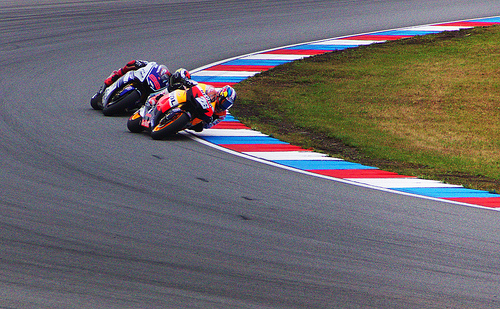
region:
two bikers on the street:
[79, 28, 240, 180]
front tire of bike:
[144, 98, 201, 151]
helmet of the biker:
[211, 74, 243, 116]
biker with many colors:
[129, 82, 248, 156]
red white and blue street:
[268, 135, 388, 203]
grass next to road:
[313, 85, 406, 142]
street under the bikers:
[82, 145, 192, 230]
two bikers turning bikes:
[71, 54, 263, 161]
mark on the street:
[159, 160, 239, 220]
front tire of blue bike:
[103, 81, 143, 113]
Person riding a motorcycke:
[70, 42, 161, 104]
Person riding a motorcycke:
[135, 63, 218, 145]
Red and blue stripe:
[322, 153, 376, 193]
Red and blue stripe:
[423, 177, 498, 234]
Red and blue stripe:
[220, 40, 262, 91]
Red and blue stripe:
[256, 27, 321, 89]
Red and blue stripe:
[327, 15, 374, 69]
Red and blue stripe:
[369, 10, 429, 53]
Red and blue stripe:
[440, 9, 477, 51]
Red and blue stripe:
[238, 117, 293, 179]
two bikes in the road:
[90, 16, 312, 208]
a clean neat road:
[1, 106, 369, 306]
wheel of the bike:
[148, 113, 200, 142]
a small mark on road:
[183, 159, 233, 201]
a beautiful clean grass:
[264, 46, 476, 211]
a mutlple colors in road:
[234, 129, 493, 229]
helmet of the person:
[212, 88, 244, 110]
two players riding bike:
[63, 1, 275, 187]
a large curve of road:
[62, 5, 435, 255]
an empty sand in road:
[400, 59, 499, 161]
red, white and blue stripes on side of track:
[179, 12, 497, 219]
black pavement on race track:
[1, 0, 496, 307]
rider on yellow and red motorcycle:
[127, 83, 236, 138]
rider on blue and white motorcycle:
[90, 60, 188, 120]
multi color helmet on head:
[217, 85, 234, 109]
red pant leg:
[101, 58, 146, 87]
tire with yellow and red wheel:
[150, 105, 191, 139]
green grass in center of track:
[227, 23, 498, 191]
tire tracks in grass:
[235, 98, 361, 160]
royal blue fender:
[116, 85, 136, 97]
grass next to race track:
[226, 22, 498, 189]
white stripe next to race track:
[355, 178, 452, 185]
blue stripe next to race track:
[271, 158, 375, 169]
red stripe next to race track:
[311, 167, 401, 177]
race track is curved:
[1, 1, 499, 307]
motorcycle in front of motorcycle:
[126, 77, 234, 137]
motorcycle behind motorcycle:
[91, 56, 189, 116]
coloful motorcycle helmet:
[218, 83, 234, 110]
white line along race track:
[182, 129, 498, 216]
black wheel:
[151, 110, 192, 138]